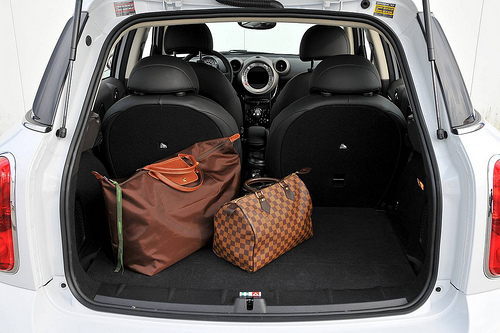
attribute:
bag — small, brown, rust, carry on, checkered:
[209, 169, 321, 276]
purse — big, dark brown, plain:
[92, 130, 247, 276]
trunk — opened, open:
[50, 4, 457, 320]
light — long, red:
[485, 153, 499, 278]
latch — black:
[56, 2, 89, 141]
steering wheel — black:
[184, 45, 236, 85]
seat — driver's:
[162, 24, 241, 138]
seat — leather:
[260, 49, 415, 211]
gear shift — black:
[243, 125, 269, 148]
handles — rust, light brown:
[141, 150, 211, 195]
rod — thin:
[420, 1, 449, 143]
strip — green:
[113, 176, 127, 276]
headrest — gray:
[119, 53, 202, 98]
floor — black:
[318, 197, 407, 279]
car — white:
[0, 0, 495, 330]